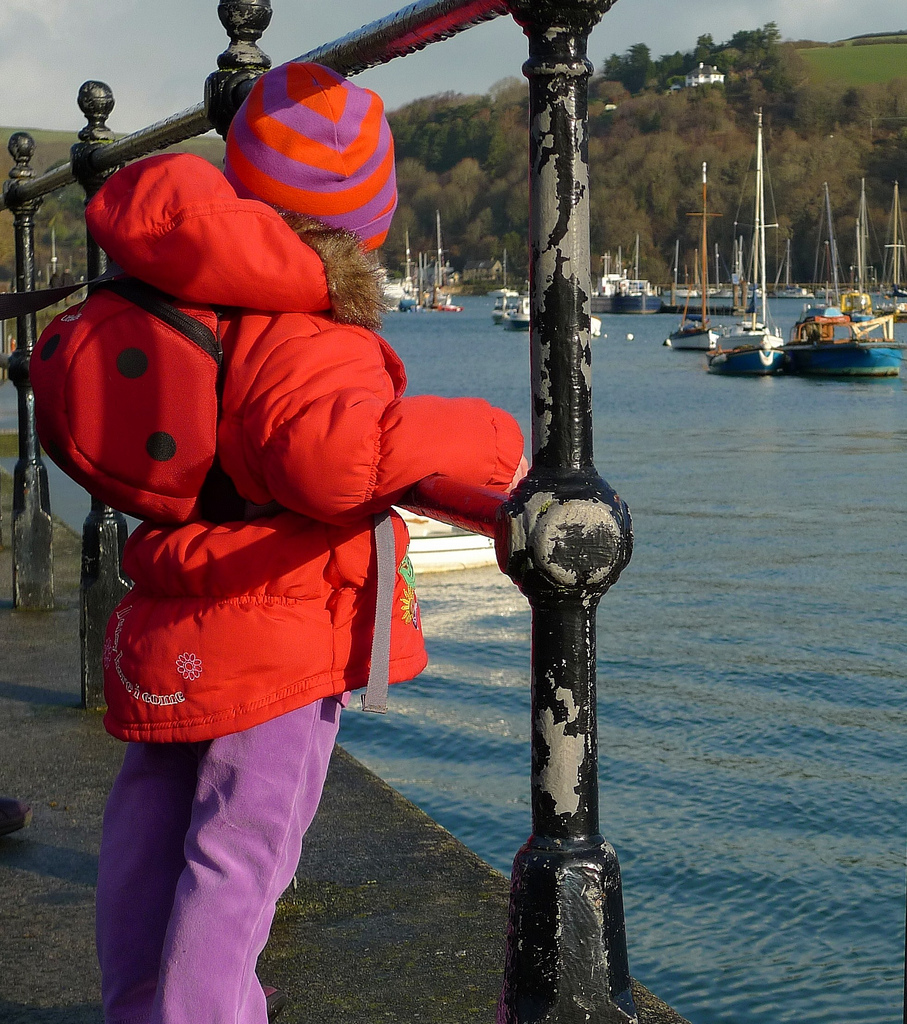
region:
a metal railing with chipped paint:
[484, 1, 699, 1006]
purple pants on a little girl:
[74, 618, 410, 1020]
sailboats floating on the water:
[658, 140, 905, 447]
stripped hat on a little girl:
[190, 37, 430, 313]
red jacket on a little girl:
[32, 152, 560, 770]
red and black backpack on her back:
[17, 240, 263, 563]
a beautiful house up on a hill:
[638, 37, 793, 135]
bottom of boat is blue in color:
[773, 241, 897, 453]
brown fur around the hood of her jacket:
[160, 96, 483, 369]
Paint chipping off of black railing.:
[524, 78, 610, 885]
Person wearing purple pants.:
[101, 767, 300, 1018]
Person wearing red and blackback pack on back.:
[34, 281, 250, 525]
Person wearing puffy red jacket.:
[79, 168, 422, 714]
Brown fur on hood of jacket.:
[299, 216, 419, 337]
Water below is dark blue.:
[651, 697, 854, 988]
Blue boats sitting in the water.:
[750, 334, 891, 374]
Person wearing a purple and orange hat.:
[239, 80, 400, 247]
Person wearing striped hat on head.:
[231, 65, 405, 230]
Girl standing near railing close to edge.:
[47, 210, 636, 749]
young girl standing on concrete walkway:
[2, 60, 687, 1020]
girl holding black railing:
[0, 2, 640, 1020]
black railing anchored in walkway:
[0, 3, 686, 1020]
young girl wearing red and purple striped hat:
[90, 61, 533, 1019]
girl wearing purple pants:
[99, 57, 534, 1015]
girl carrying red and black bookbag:
[33, 54, 529, 1020]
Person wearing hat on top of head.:
[227, 57, 440, 275]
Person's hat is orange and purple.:
[218, 69, 392, 252]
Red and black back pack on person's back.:
[14, 292, 235, 492]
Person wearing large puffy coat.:
[58, 237, 423, 737]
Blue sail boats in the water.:
[721, 329, 897, 395]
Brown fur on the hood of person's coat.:
[274, 202, 385, 318]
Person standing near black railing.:
[122, 47, 614, 566]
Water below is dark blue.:
[627, 394, 857, 979]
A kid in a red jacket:
[91, 167, 477, 638]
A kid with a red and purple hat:
[178, 25, 373, 256]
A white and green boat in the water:
[654, 299, 723, 383]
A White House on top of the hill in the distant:
[647, 47, 736, 155]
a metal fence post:
[499, 0, 635, 1021]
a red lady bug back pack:
[35, 288, 226, 530]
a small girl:
[87, 64, 524, 1021]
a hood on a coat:
[88, 155, 386, 328]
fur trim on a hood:
[280, 200, 386, 333]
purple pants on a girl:
[101, 691, 353, 1021]